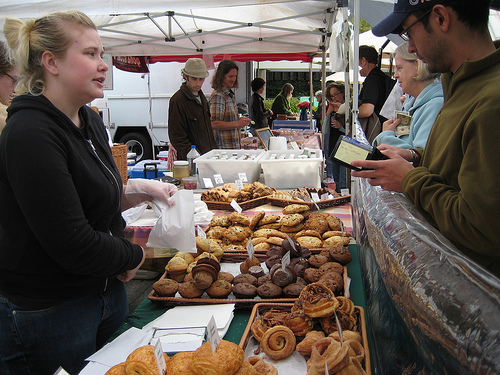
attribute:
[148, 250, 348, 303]
tray — white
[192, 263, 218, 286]
muffin — baked, for sale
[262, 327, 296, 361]
donut — baked, frosted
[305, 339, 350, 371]
donut — baked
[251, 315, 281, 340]
donut — baked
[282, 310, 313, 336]
donut — baked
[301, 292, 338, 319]
donut — baked, frosted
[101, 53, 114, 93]
sign — white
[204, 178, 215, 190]
sign — white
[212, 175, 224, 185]
sign — white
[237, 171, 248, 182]
sign — white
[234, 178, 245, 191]
sign — white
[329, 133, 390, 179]
wallet — open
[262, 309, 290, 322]
donut — delicious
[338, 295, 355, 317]
donut — delicious, baked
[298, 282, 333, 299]
donut — delicious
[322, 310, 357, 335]
donut — delicious, for sale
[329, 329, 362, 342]
donut — delicious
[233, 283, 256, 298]
muffin — chocolate, for sale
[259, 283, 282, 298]
muffin — chocolate, brown, for sale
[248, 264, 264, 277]
muffin — chocolate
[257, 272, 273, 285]
muffin — chocolate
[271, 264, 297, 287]
muffin — chocolate, brown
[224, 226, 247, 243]
cookie — chocolate chip, stacked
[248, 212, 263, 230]
cookie — freshly baked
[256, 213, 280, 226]
cookie — freshly baked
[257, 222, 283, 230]
cookie — freshly baked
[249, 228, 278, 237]
cookie — freshly baked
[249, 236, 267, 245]
cookie — freshly baked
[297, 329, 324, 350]
donut — tasty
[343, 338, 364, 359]
donut — tasty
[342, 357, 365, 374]
donut — tasty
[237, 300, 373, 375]
tray — white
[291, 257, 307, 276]
muffin — brown, for sale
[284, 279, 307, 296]
muffin — brown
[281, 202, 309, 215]
cookie — chocolate chip, stacked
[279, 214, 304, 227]
cookie — chocolate chip, stacked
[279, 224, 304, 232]
cookie — chocolate chip, stacked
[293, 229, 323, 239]
cookie — chocolate chip, stacked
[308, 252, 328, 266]
muffin — freshly baked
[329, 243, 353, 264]
muffin — freshly baked, for sale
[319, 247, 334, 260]
muffin — freshly baked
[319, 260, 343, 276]
muffin — freshly baked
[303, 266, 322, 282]
muffin — freshly baked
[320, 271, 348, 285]
muffin — for sale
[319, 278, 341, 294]
muffin — for sale, brown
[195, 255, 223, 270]
muffin — chocolate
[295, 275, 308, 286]
muffin — chocolate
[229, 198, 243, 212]
sign — white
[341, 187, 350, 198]
sign — white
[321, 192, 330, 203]
sign — white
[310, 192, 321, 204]
sign — white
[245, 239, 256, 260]
sign — white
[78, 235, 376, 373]
counter — covered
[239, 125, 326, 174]
counter — covered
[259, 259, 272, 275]
sign — white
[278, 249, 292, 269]
sign — white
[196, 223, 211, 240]
sign — white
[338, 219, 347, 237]
sign — white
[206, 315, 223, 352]
sign — white